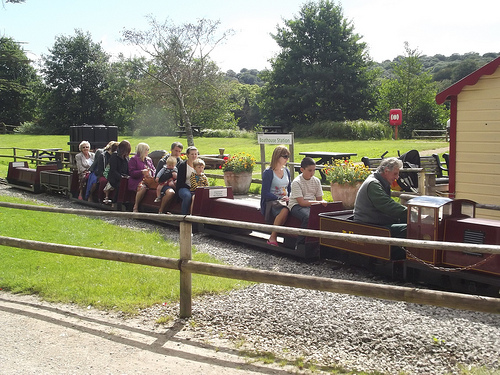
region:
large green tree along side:
[261, 2, 387, 124]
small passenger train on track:
[11, 107, 490, 279]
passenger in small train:
[356, 152, 406, 223]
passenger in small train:
[291, 159, 320, 210]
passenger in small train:
[265, 145, 295, 213]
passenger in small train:
[187, 162, 212, 200]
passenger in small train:
[182, 145, 194, 197]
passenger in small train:
[130, 140, 150, 190]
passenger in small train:
[75, 140, 95, 187]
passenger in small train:
[111, 135, 130, 195]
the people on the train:
[72, 140, 413, 257]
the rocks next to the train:
[230, 270, 440, 354]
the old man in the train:
[357, 160, 406, 227]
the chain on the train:
[395, 245, 499, 272]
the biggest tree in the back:
[251, 3, 397, 145]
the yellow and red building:
[434, 47, 499, 202]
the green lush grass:
[11, 207, 157, 304]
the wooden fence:
[5, 189, 497, 339]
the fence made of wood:
[1, 185, 496, 330]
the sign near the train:
[251, 129, 301, 189]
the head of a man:
[373, 154, 409, 188]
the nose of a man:
[391, 170, 401, 180]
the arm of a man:
[366, 182, 408, 219]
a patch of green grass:
[0, 190, 262, 314]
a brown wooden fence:
[1, 198, 499, 333]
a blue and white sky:
[1, 0, 498, 70]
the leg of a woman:
[266, 205, 296, 241]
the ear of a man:
[380, 163, 390, 175]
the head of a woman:
[266, 142, 294, 170]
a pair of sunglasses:
[277, 150, 297, 162]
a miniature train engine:
[406, 189, 498, 292]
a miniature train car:
[322, 196, 407, 278]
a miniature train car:
[202, 179, 321, 251]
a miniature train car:
[132, 160, 230, 237]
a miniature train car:
[70, 149, 137, 206]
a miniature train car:
[42, 154, 76, 189]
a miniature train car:
[9, 149, 60, 194]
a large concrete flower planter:
[325, 159, 365, 205]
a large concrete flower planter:
[220, 157, 250, 192]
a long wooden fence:
[2, 194, 497, 323]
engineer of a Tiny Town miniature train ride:
[315, 154, 499, 301]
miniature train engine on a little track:
[403, 194, 499, 305]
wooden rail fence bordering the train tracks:
[3, 194, 499, 321]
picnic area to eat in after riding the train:
[298, 145, 443, 190]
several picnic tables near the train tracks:
[173, 119, 358, 164]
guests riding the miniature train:
[68, 135, 215, 210]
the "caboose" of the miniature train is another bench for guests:
[2, 154, 67, 194]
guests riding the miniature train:
[252, 145, 344, 240]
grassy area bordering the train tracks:
[2, 128, 357, 193]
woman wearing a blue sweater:
[255, 144, 299, 241]